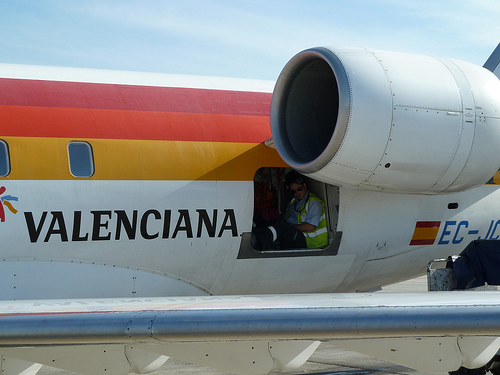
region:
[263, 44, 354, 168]
silver ring on the the engine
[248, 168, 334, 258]
person squeezed in a small hole on plane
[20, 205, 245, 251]
valenciana on the side of the plane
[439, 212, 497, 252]
ec-jg in blue writing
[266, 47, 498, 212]
engine of the plane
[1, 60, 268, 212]
red maroon and orange stripe on plane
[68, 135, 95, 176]
window on the side of the plane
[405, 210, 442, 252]
red and orange box on plane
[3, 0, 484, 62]
blue sky with clouds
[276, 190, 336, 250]
Man is wearing a vest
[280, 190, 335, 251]
Man wearing a green vest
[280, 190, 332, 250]
Man is wearing a green vest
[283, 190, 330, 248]
Man wearing a reflective vest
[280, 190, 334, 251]
Man is wearing a reflective vest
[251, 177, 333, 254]
Man sitting in an airplane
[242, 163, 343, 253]
Man is sitting in a plane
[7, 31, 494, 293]
plane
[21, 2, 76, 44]
white clouds in blue sky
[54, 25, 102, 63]
white clouds in blue sky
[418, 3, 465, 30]
white clouds in blue sky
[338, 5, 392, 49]
white clouds in blue sky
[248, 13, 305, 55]
white clouds in blue sky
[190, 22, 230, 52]
white clouds in blue sky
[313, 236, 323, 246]
man wearing green vest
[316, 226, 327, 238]
white strip on vest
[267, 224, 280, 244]
white strip on pants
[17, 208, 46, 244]
letter v on plane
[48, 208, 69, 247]
letter a on plane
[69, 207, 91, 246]
letter l on plane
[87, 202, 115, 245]
letter e on plane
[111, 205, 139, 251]
letter n on plane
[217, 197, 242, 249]
The letter is black.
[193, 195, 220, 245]
The letter is black.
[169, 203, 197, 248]
The letter is black.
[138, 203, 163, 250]
The letter is black.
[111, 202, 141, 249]
The letter is black.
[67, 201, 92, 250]
The letter is black.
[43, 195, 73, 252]
The letter is black.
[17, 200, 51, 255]
The letter is black.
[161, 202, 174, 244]
The letter is black.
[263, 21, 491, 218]
large engine on side of plane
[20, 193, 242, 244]
word that says valenciana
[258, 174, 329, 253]
crew member that is inside the plane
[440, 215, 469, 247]
park of plane that says EC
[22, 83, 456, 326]
the plane is large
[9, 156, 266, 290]
the text says VALENCIANA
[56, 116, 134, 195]
the window is small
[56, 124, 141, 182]
the small window is glass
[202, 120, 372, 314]
the door is open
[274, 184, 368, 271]
the person is sitting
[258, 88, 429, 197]
the engine is large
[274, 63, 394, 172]
the engine is silver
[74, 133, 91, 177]
a window on an airplane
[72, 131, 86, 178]
a window on a plane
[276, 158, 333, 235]
a person sitting in the plane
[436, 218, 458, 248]
e on the plane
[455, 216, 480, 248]
c on the plane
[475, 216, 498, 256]
j on the plane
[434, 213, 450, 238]
e on the airplane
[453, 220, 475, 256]
c on the airplane